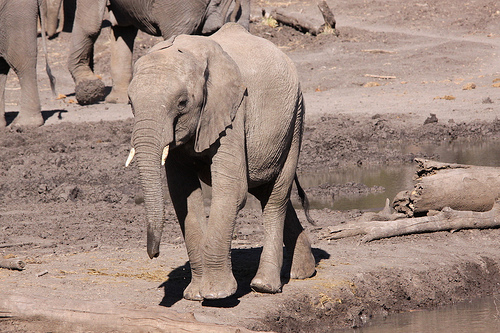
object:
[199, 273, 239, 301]
foot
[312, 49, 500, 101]
dirt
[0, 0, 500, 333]
ground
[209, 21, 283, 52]
back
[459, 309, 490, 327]
ripple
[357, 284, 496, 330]
water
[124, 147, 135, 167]
tusk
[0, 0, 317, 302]
elephant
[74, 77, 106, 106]
hoof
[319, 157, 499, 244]
log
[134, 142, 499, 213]
water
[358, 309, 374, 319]
holes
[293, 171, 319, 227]
tail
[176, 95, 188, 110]
eye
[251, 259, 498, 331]
watering hole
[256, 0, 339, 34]
rock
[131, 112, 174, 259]
trunk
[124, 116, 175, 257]
trunk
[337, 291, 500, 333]
water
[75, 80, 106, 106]
mud